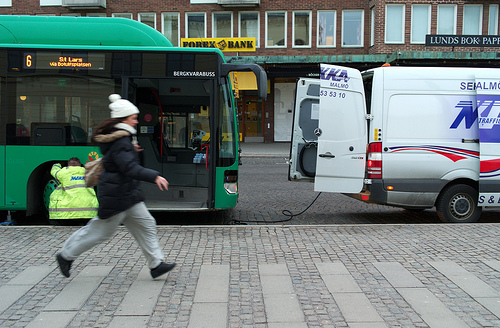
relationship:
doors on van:
[298, 65, 372, 212] [321, 60, 484, 224]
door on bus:
[161, 78, 215, 189] [55, 21, 247, 226]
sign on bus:
[46, 55, 100, 91] [55, 21, 247, 226]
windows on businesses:
[220, 8, 396, 61] [226, 1, 473, 113]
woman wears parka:
[81, 106, 170, 264] [105, 116, 138, 142]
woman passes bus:
[81, 106, 170, 264] [55, 21, 247, 226]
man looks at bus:
[56, 147, 102, 211] [55, 21, 247, 226]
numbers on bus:
[19, 52, 52, 92] [55, 21, 247, 226]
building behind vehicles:
[182, 1, 409, 86] [2, 16, 467, 219]